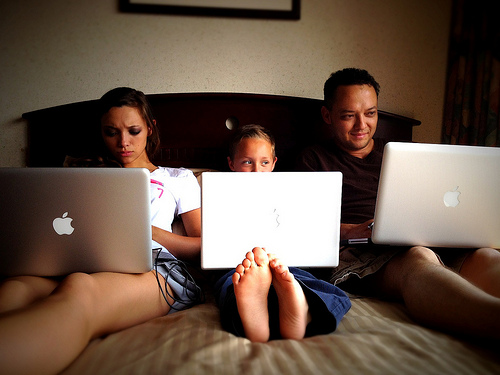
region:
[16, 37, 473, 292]
3 people on laptops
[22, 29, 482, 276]
3 people in bed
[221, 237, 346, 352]
a pair of feet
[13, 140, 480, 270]
3 apple laptops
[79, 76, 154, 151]
a young girl wearing eyeshadow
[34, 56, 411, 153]
a bed headboard in dark wood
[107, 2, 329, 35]
a framed picture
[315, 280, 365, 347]
loose blue pants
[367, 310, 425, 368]
a striped duvet cover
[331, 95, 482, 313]
a man wearing shorts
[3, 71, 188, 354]
"woman with a laptop"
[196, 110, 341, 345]
"girl with laptop"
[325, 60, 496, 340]
" man with laptop"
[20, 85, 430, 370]
" bed with brown headboard"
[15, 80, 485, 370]
"bed with tan stripe sheets"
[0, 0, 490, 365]
"white wall with picture"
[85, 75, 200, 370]
"woman with white top and blue skirt"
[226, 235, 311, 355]
"girls bare feet"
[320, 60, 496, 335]
" man wearing brown shirt and tan shorts"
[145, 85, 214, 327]
" computer wires"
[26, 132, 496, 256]
three gray laptops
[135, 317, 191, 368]
brown stripes in a sheet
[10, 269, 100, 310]
a woman's kneecaps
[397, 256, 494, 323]
a man's hairy legs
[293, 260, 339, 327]
blue pants on a child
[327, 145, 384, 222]
black shirt on a man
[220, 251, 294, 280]
a child's bare toes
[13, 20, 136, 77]
a tan speckled wall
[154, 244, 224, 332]
a black charging cord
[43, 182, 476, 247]
three Apple logos on laptops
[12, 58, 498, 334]
three people relaxing in bed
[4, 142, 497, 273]
three laptops in people's laps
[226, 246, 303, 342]
the bottom of a child's bare feet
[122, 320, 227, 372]
brown striped sheets on the bed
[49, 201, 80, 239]
the Apple logo on the back of a laptop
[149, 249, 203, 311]
a black charger cord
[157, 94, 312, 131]
a brown wooden head board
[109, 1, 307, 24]
a picture frame on the wall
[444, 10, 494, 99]
a window curtain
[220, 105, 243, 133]
a round hole in the head board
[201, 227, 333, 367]
a young girls feet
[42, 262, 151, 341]
the knee of a woman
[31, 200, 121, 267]
logo on a laptop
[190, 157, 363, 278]
a silver laptop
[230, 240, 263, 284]
the toes of a girl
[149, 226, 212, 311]
a black computer cord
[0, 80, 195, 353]
a woman sitting in bed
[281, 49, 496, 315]
a man sitting in bed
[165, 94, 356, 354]
a young girl sitting in bed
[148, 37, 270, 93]
a white wall behind the bed